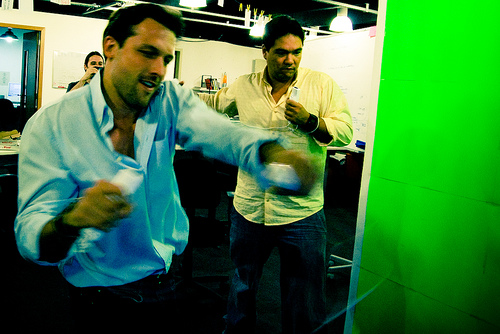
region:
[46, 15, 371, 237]
Three people are in picture.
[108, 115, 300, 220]
Man is holding Wii in both the hands.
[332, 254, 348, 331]
Floor is black color.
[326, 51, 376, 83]
Wall is white color.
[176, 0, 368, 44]
Lights are in ceiling.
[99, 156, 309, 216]
Wii is white color.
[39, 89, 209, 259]
Man is wearing blue shirt.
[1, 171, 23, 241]
Chair is black color.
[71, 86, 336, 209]
Three Wii is seen in picture.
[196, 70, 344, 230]
Man is wearing tan color shirt.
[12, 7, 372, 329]
two men playing Wii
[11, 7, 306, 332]
man on left wears blue shirt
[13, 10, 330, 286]
man on left holds Wii controllers in both hands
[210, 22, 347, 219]
man on right wears light yellow shirt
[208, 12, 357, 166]
man on right wears black band on left wrist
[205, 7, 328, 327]
man on right wears blue jeans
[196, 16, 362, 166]
man on right holds Wii controller in left hand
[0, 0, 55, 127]
open door in the background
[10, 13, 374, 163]
white walls in the background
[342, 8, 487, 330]
neon green wall on the right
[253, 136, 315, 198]
human hand holding a wii controller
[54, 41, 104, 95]
man standing behind men playing wii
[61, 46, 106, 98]
man taking a picture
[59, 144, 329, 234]
two human hands in motion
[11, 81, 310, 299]
long sleeved blue shirt that has been rolled up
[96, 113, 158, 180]
first few buttons on the collar are open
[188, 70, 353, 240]
long sleeved yellow shirt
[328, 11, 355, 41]
light fixture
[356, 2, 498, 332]
lime green wall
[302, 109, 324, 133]
Black watch on a man's left hand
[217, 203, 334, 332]
Mans' blue jeans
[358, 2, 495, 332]
Green cover on a wall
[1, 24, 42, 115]
Open door on a wall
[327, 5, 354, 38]
Light on a ceiling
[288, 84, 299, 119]
White wii mote in a man's hand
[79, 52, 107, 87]
Man holding a camera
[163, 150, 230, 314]
Chair on wheels between two men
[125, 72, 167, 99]
Smile on a man's face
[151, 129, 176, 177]
Pocket on a man's shirt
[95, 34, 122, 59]
an ear of a man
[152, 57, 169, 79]
a nose of a man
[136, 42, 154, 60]
an eye of a man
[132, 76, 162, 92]
a mouth on a face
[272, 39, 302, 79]
the face of a man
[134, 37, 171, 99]
the face of a man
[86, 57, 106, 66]
the eyes of a man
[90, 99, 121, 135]
a collar on a shirt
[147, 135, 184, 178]
a pocket on a shirt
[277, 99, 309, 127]
a hand of a man